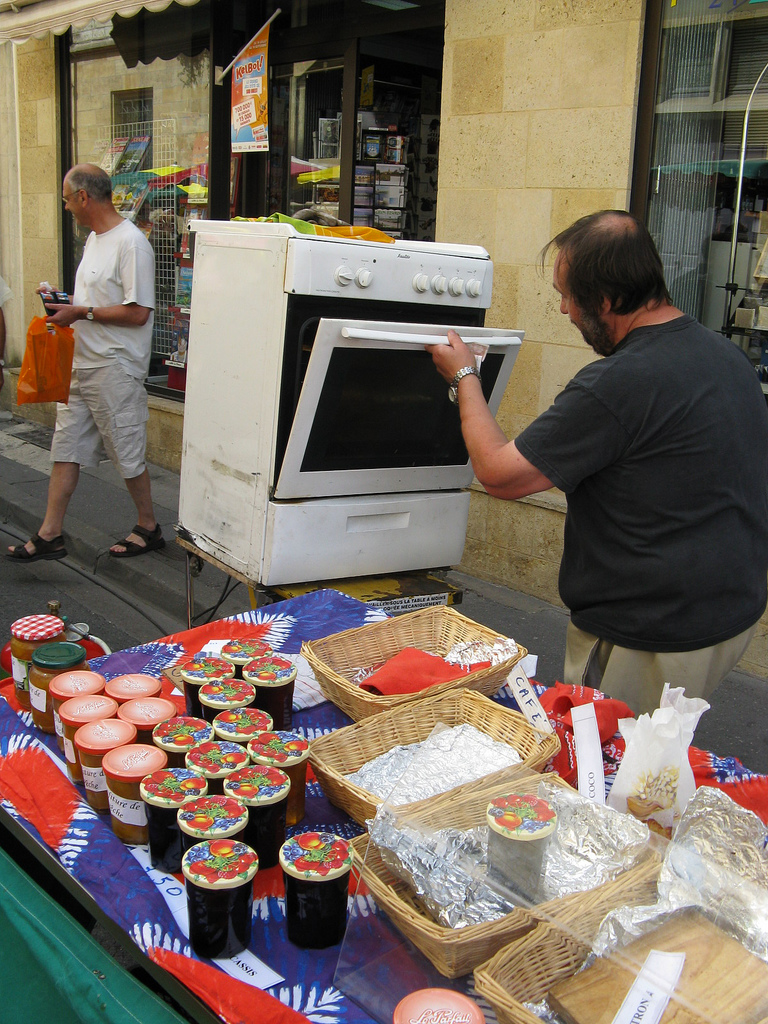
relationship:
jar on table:
[279, 828, 354, 948] [0, 710, 766, 1019]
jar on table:
[272, 820, 359, 955] [0, 587, 763, 1018]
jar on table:
[179, 836, 259, 958] [0, 587, 763, 1018]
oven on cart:
[163, 187, 531, 600] [171, 527, 461, 631]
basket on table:
[299, 605, 529, 725] [0, 587, 763, 1018]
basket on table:
[310, 687, 562, 828] [0, 587, 763, 1018]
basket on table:
[346, 770, 662, 978] [0, 587, 763, 1018]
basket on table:
[477, 859, 763, 1018] [0, 587, 763, 1018]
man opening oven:
[428, 213, 763, 719] [176, 220, 525, 585]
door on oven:
[272, 317, 524, 502] [176, 220, 525, 585]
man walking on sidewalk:
[4, 164, 167, 559] [0, 407, 763, 771]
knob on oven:
[332, 262, 354, 287] [163, 187, 531, 600]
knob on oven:
[350, 264, 372, 290] [163, 187, 531, 600]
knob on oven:
[413, 276, 428, 291] [163, 187, 531, 600]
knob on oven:
[433, 276, 455, 295] [163, 187, 531, 600]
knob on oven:
[451, 276, 466, 295] [163, 187, 531, 600]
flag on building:
[220, 10, 278, 155] [4, 2, 763, 676]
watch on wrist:
[447, 368, 480, 401] [440, 370, 480, 385]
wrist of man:
[440, 370, 480, 385] [428, 213, 763, 719]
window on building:
[636, 0, 763, 390] [4, 2, 763, 676]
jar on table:
[11, 609, 66, 705] [0, 587, 763, 1018]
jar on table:
[279, 828, 354, 948] [0, 587, 763, 1018]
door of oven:
[272, 317, 524, 502] [176, 220, 525, 585]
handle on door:
[293, 265, 515, 401] [290, 301, 524, 587]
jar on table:
[226, 759, 295, 870] [0, 587, 763, 1018]